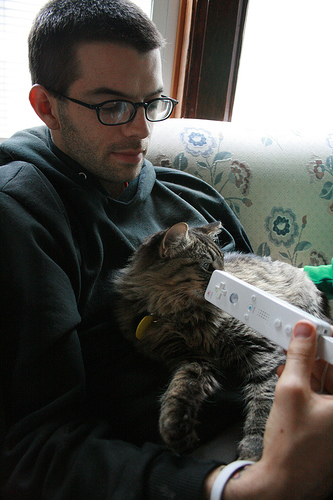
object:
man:
[0, 0, 333, 500]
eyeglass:
[55, 91, 179, 127]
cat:
[109, 220, 330, 463]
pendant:
[135, 314, 153, 339]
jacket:
[0, 126, 255, 500]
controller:
[203, 268, 332, 366]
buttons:
[244, 314, 249, 321]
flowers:
[264, 205, 300, 249]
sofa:
[144, 117, 333, 269]